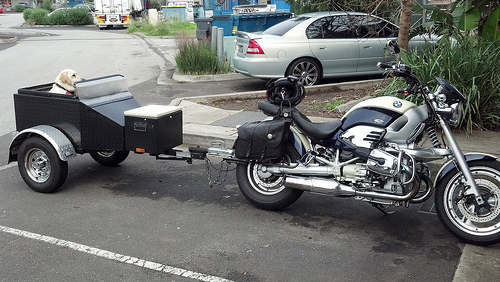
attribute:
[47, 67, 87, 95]
dog — sitting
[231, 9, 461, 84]
car — grey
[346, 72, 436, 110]
grass — tall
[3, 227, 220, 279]
line — solid, white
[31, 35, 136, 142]
dog — white, sitting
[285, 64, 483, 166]
emblem — bmw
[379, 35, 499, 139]
grass — tall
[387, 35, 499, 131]
grass — tall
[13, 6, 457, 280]
street — black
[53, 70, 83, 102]
dog — black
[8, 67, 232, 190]
trailer — small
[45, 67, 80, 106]
lab — yellow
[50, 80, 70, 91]
collar — black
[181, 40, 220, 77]
grass — tall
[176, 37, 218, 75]
grass — tall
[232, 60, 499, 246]
motorcycle — black, white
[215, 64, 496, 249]
motorcycle — silver, black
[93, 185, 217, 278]
sidewalk — small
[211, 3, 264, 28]
dumpster — small, blue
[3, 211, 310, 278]
line — white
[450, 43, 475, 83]
grass — tall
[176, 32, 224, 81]
bush — green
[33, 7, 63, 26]
grass — tall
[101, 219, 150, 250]
patch — small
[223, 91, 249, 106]
dirt patch — small